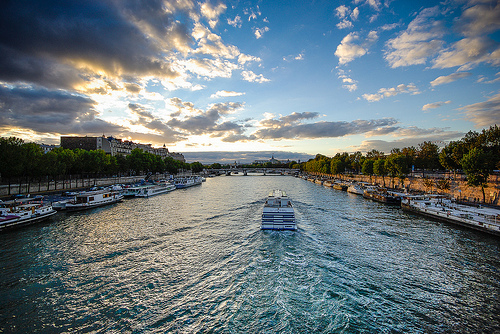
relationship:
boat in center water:
[259, 185, 299, 234] [1, 170, 496, 331]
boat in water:
[1, 196, 60, 231] [1, 170, 496, 331]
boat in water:
[55, 185, 123, 214] [1, 170, 496, 331]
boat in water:
[123, 178, 176, 198] [1, 170, 496, 331]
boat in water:
[173, 167, 203, 187] [1, 170, 496, 331]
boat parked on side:
[302, 170, 314, 184] [282, 177, 497, 231]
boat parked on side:
[312, 171, 328, 188] [282, 177, 497, 231]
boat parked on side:
[320, 177, 337, 192] [282, 177, 497, 231]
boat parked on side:
[347, 177, 370, 202] [282, 177, 497, 231]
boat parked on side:
[365, 177, 404, 211] [282, 177, 497, 231]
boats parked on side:
[2, 163, 205, 243] [1, 157, 206, 268]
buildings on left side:
[58, 135, 171, 163] [0, 0, 253, 332]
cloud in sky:
[2, 1, 217, 99] [0, 0, 499, 159]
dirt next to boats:
[455, 182, 495, 202] [393, 182, 498, 237]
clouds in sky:
[347, 12, 432, 71] [0, 0, 499, 159]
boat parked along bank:
[1, 196, 60, 231] [0, 175, 193, 203]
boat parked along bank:
[52, 185, 123, 211] [0, 175, 193, 203]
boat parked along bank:
[123, 178, 176, 198] [0, 175, 193, 203]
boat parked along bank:
[173, 167, 203, 188] [0, 175, 193, 203]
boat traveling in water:
[259, 185, 297, 230] [1, 170, 496, 331]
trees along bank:
[304, 124, 499, 184] [339, 182, 442, 237]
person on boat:
[266, 202, 269, 205] [259, 185, 297, 230]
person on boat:
[286, 200, 289, 205] [259, 185, 297, 230]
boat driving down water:
[259, 185, 297, 230] [234, 240, 366, 327]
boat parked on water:
[1, 196, 60, 231] [1, 170, 496, 331]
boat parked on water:
[52, 185, 123, 211] [1, 170, 496, 331]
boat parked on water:
[123, 178, 176, 198] [1, 170, 496, 331]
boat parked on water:
[173, 171, 199, 188] [1, 170, 496, 331]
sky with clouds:
[131, 10, 400, 109] [353, 10, 472, 92]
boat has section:
[259, 185, 297, 230] [266, 185, 289, 198]